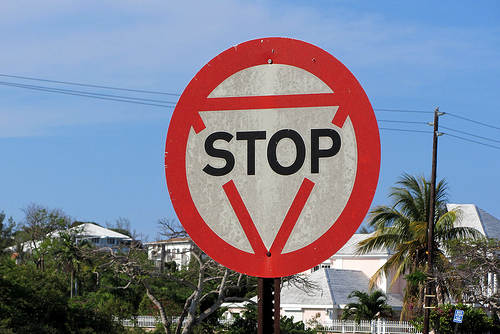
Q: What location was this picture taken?
A: Tropical location.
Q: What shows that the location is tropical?
A: Palm trees.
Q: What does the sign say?
A: Stop.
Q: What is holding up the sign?
A: A rusty pole.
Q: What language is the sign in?
A: It is in English.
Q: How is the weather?
A: It is clear.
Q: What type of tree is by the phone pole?
A: A palm tree.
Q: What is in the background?
A: Trees and houses.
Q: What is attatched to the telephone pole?
A: Wires.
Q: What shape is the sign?
A: It is round.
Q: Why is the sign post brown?
A: It has rusted.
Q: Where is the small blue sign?
A: It is in the lower right corner.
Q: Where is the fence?
A: It is in front of the houses.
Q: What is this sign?
A: A stop sign.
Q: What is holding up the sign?
A: A pole.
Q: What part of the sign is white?
A: The center.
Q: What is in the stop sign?
A: A triangle.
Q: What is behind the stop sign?
A: Power lines.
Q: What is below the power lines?
A: A palm tree.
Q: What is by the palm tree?
A: A house.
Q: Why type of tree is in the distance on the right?
A: Palm.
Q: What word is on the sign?
A: Stop.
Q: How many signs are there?
A: 1.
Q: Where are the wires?
A: In the sky.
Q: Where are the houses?
A: Behind the sign.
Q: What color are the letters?
A: Black.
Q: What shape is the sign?
A: Circle.